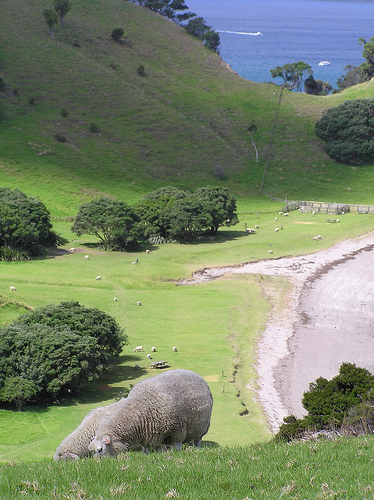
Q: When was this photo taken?
A: In the daytime.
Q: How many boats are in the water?
A: Two.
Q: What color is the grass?
A: Green.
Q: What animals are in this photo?
A: Sheep.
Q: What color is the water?
A: Blue.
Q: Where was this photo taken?
A: In a field.